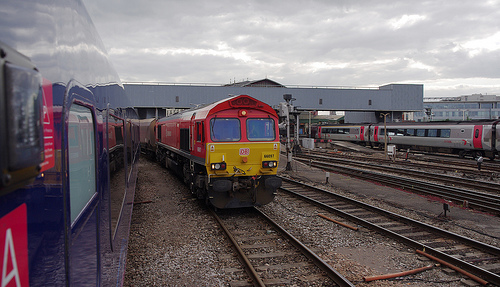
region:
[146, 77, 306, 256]
the train is red and yellow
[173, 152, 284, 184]
the lights on the side are on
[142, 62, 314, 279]
the train is moving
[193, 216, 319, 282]
rocks on the track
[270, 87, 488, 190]
a train to the right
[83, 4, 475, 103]
the sky is overcast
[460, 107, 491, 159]
the door is red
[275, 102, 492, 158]
the train is grey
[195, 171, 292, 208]
the bumpers are black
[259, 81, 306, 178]
the pole is grey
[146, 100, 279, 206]
red and yellow train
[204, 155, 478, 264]
sets of train tracks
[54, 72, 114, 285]
door on the side of a train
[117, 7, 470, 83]
very cloudy grey sky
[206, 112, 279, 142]
pair of windows at the front of the train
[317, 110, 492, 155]
grey train with red doors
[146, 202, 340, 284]
stones around the tracks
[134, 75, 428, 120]
long building over the tracks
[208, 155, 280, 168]
pair of small headlights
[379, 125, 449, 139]
row of windows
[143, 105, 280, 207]
the train is on the tracks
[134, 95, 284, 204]
the train is in the station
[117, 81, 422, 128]
the building is blue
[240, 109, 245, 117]
the light of the train is on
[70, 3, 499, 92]
the sky is very cloudy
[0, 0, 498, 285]
many trains in the station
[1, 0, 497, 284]
three trains in the station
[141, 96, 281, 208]
the front of the train is yellow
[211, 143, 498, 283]
many train tracks in station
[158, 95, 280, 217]
a red and yellow train engine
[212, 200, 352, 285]
a set of train tracks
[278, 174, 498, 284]
a set of train tracks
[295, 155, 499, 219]
a set of train tracks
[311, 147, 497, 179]
a set of train tracks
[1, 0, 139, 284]
a blue train passenger car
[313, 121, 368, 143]
a silver and red passenger train car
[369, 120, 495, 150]
a silver and red passenger train car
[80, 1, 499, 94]
a cloudy white sky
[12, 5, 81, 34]
white clouds in blue sky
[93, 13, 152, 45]
white clouds in blue sky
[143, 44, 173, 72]
white clouds in blue sky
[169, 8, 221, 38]
white clouds in blue sky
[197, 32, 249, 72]
white clouds in blue sky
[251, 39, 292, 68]
white clouds in blue sky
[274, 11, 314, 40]
white clouds in blue sky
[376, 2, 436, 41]
white clouds in blue sky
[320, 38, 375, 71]
white clouds in blue sky